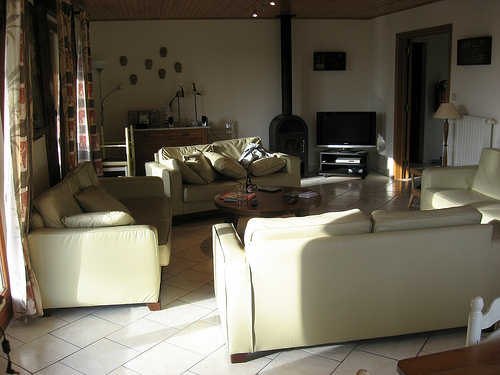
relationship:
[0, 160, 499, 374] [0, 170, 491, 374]
tiles on floor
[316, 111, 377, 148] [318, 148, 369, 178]
television has stand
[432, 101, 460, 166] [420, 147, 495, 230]
lamp near couch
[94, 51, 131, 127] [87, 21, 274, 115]
lamp has wall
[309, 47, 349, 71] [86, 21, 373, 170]
frames on wall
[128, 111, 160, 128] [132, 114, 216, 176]
stereo on cabinet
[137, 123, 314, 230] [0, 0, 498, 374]
sofa in room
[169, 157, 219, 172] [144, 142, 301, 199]
cushion in sofa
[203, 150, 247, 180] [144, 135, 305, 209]
pillows in sofa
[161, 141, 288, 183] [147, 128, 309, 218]
pillows on sofa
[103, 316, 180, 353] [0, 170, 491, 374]
tile on floor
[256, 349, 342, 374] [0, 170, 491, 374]
tile on floor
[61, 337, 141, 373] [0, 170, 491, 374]
tile on floor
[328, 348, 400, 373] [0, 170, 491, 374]
tile on floor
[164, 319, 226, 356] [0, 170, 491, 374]
tile on floor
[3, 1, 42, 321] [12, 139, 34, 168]
curtain have flower